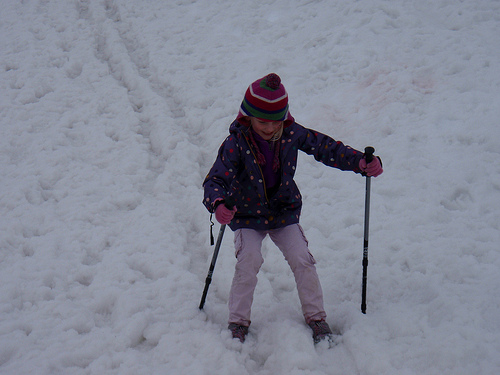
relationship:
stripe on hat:
[247, 81, 287, 103] [227, 71, 294, 123]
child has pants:
[201, 71, 383, 349] [221, 221, 328, 326]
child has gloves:
[201, 71, 383, 349] [212, 200, 233, 224]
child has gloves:
[201, 71, 383, 349] [355, 153, 382, 179]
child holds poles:
[201, 71, 383, 349] [171, 139, 393, 325]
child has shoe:
[201, 71, 383, 349] [307, 319, 334, 349]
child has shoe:
[201, 71, 383, 349] [226, 320, 248, 345]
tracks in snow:
[100, 41, 224, 183] [17, 24, 235, 209]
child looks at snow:
[201, 71, 383, 349] [0, 0, 497, 371]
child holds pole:
[201, 71, 383, 349] [362, 145, 378, 314]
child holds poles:
[201, 71, 383, 349] [199, 197, 238, 311]